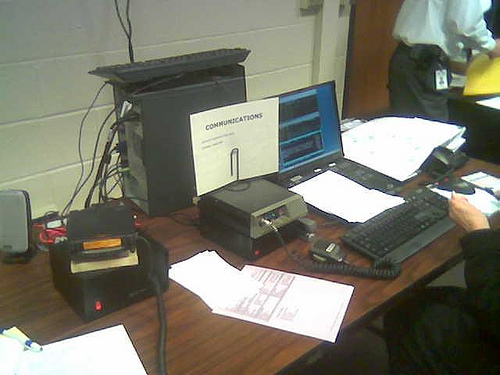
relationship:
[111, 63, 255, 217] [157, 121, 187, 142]
computer has cpu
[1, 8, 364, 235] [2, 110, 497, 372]
wall behind desk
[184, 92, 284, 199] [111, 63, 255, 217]
sign in front of computer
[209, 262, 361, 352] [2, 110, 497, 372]
paper on desk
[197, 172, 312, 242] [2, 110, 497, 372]
cb radio on desk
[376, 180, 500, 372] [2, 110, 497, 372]
man sitting at desk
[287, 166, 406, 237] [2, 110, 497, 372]
paper on table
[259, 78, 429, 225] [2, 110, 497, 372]
computer on desk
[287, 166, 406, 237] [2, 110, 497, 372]
paper on desk